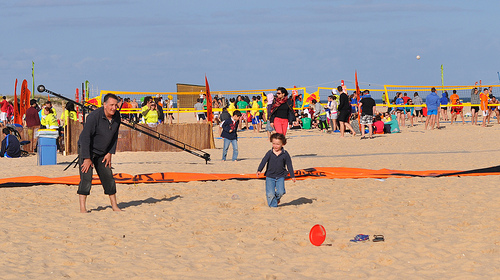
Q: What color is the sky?
A: Blue.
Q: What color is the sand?
A: Brown.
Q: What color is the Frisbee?
A: Orange.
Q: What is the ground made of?
A: Sand.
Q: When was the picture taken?
A: Daytime.